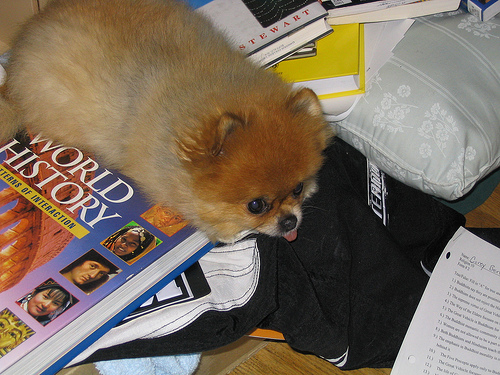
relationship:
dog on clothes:
[186, 94, 313, 207] [232, 260, 399, 347]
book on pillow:
[7, 145, 191, 338] [373, 26, 488, 205]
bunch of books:
[251, 13, 431, 108] [219, 19, 312, 81]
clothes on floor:
[232, 260, 399, 347] [262, 349, 299, 368]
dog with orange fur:
[186, 94, 313, 207] [230, 135, 289, 177]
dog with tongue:
[186, 94, 313, 207] [280, 229, 303, 245]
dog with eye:
[186, 94, 313, 207] [238, 193, 289, 240]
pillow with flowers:
[373, 26, 488, 205] [381, 94, 448, 124]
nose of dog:
[270, 212, 313, 246] [186, 94, 313, 207]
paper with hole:
[438, 240, 461, 274] [445, 240, 499, 317]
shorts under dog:
[311, 214, 406, 337] [186, 94, 313, 207]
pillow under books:
[373, 26, 488, 205] [219, 19, 312, 81]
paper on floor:
[438, 240, 461, 274] [262, 349, 299, 368]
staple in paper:
[449, 220, 471, 246] [438, 240, 461, 274]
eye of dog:
[238, 193, 289, 240] [186, 94, 313, 207]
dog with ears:
[186, 94, 313, 207] [197, 96, 351, 135]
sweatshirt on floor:
[304, 261, 357, 332] [262, 349, 299, 368]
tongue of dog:
[280, 229, 303, 245] [186, 94, 313, 207]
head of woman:
[105, 229, 148, 271] [96, 228, 171, 275]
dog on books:
[186, 94, 313, 207] [219, 19, 312, 81]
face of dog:
[232, 133, 328, 253] [186, 94, 313, 207]